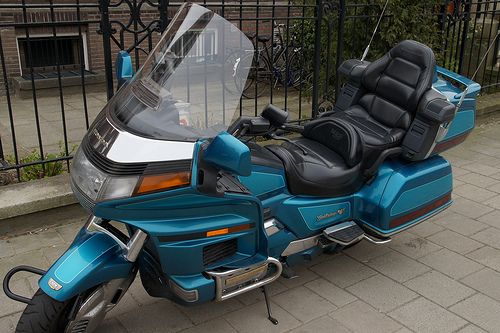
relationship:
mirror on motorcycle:
[213, 135, 250, 174] [12, 25, 481, 331]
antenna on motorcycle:
[455, 2, 498, 87] [0, 0, 482, 333]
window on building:
[17, 31, 88, 79] [1, 0, 359, 97]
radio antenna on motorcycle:
[358, 1, 384, 60] [12, 25, 481, 331]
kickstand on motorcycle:
[250, 288, 286, 327] [0, 0, 482, 333]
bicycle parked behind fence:
[230, 17, 323, 99] [2, 2, 497, 207]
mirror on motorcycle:
[112, 49, 133, 85] [0, 0, 482, 333]